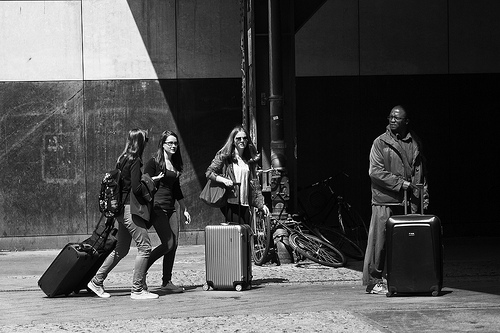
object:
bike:
[309, 167, 372, 255]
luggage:
[384, 214, 441, 297]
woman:
[87, 128, 166, 301]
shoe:
[130, 290, 160, 300]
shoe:
[86, 280, 110, 301]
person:
[144, 129, 193, 293]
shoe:
[160, 283, 186, 293]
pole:
[267, 2, 300, 265]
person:
[196, 125, 271, 287]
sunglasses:
[234, 136, 249, 141]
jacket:
[369, 125, 429, 208]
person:
[362, 106, 431, 296]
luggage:
[205, 222, 253, 290]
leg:
[87, 214, 132, 297]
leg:
[120, 206, 161, 300]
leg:
[145, 206, 175, 288]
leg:
[159, 208, 186, 293]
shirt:
[232, 154, 249, 209]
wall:
[1, 0, 498, 238]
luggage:
[38, 239, 101, 298]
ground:
[1, 245, 500, 333]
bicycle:
[267, 208, 368, 267]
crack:
[1, 81, 84, 162]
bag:
[97, 157, 142, 218]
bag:
[200, 147, 233, 207]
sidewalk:
[1, 276, 499, 332]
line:
[78, 0, 90, 234]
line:
[176, 7, 180, 236]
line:
[355, 5, 364, 175]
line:
[446, 1, 454, 276]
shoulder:
[213, 152, 234, 162]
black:
[1, 75, 499, 236]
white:
[0, 0, 500, 84]